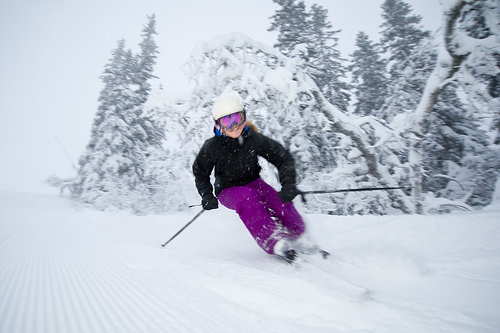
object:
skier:
[191, 85, 331, 263]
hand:
[276, 188, 298, 201]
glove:
[199, 193, 220, 209]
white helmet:
[208, 91, 246, 121]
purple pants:
[214, 178, 306, 255]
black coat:
[191, 122, 298, 198]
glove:
[277, 183, 306, 205]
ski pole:
[287, 184, 411, 196]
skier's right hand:
[199, 193, 220, 211]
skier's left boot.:
[293, 238, 330, 260]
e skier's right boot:
[273, 238, 299, 264]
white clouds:
[168, 0, 452, 193]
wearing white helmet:
[209, 88, 247, 120]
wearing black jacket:
[193, 121, 297, 199]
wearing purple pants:
[207, 176, 307, 255]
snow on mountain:
[4, 179, 499, 332]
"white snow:
[1, 214, 499, 331]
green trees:
[42, 13, 174, 212]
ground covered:
[0, 211, 499, 331]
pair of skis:
[158, 185, 416, 248]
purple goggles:
[214, 112, 248, 131]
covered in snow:
[42, 0, 499, 217]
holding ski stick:
[158, 197, 220, 249]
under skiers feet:
[281, 246, 371, 299]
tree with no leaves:
[151, 30, 426, 217]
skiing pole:
[158, 202, 210, 247]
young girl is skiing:
[160, 92, 406, 263]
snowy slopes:
[0, 198, 498, 333]